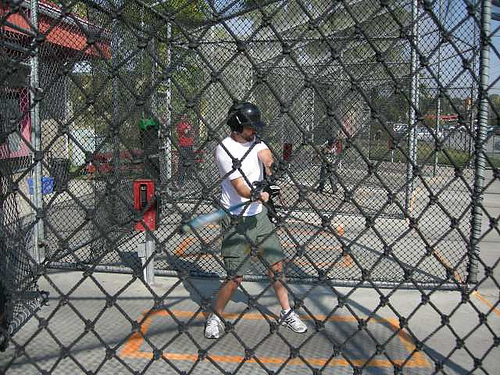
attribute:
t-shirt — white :
[206, 131, 271, 216]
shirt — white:
[209, 139, 293, 236]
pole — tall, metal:
[464, 1, 496, 293]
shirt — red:
[177, 117, 196, 146]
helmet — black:
[220, 106, 267, 131]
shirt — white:
[209, 139, 280, 221]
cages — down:
[15, 11, 482, 335]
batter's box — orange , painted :
[119, 313, 429, 374]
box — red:
[131, 172, 156, 234]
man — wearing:
[192, 97, 352, 341]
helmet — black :
[229, 98, 274, 135]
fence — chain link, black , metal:
[1, 10, 498, 367]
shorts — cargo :
[218, 214, 285, 269]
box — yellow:
[115, 300, 427, 369]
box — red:
[119, 171, 170, 288]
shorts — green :
[209, 197, 289, 273]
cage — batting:
[4, 7, 482, 347]